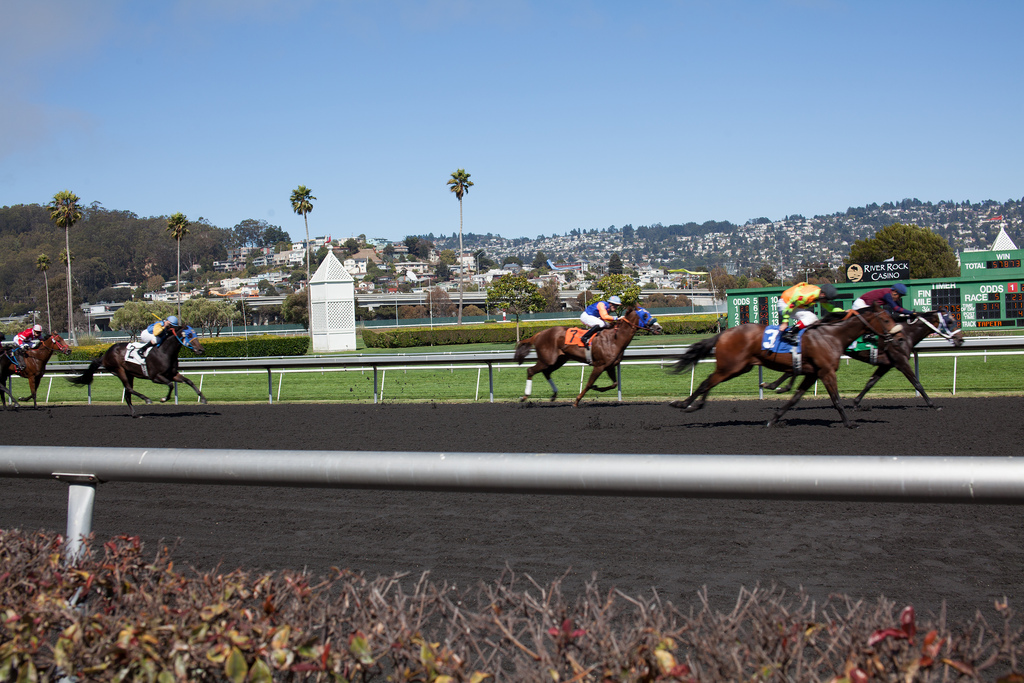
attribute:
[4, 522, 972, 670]
leaves — brown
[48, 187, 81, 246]
branch — tall, skinny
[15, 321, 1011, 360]
hedges — green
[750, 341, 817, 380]
number — blue